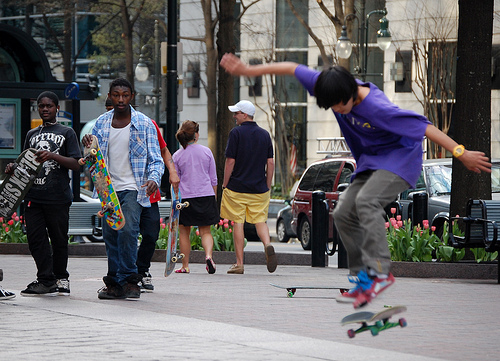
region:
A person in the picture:
[16, 79, 83, 297]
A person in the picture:
[80, 71, 166, 306]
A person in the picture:
[164, 101, 221, 276]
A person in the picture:
[216, 95, 286, 282]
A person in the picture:
[214, 40, 497, 331]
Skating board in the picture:
[337, 303, 421, 346]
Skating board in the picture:
[261, 275, 371, 307]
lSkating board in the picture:
[163, 177, 190, 284]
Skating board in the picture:
[79, 129, 126, 241]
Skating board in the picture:
[0, 127, 49, 237]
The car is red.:
[285, 143, 399, 254]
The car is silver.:
[388, 150, 499, 248]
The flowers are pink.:
[378, 199, 448, 256]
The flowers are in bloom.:
[378, 200, 488, 264]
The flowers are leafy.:
[380, 202, 497, 260]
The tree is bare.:
[403, 1, 458, 161]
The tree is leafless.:
[392, 0, 461, 159]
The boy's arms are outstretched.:
[217, 49, 497, 191]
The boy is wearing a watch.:
[222, 46, 494, 182]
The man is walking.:
[214, 95, 285, 280]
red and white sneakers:
[341, 271, 400, 306]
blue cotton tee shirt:
[292, 67, 434, 185]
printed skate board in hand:
[84, 133, 129, 231]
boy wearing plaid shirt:
[86, 81, 165, 296]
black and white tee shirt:
[22, 125, 80, 198]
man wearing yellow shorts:
[226, 98, 283, 272]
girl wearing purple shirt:
[171, 126, 219, 277]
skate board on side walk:
[276, 278, 348, 296]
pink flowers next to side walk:
[386, 209, 499, 266]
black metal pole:
[311, 188, 326, 268]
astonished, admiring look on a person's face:
[105, 81, 135, 116]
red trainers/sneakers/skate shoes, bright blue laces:
[335, 261, 403, 310]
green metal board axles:
[348, 312, 405, 338]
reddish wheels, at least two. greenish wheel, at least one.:
[342, 313, 413, 346]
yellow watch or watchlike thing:
[450, 141, 467, 159]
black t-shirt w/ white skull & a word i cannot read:
[24, 129, 69, 189]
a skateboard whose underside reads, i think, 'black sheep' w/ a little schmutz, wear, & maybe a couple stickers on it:
[0, 144, 50, 232]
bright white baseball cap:
[224, 94, 263, 118]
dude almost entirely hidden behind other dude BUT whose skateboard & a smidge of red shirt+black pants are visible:
[85, 80, 193, 305]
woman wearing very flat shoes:
[173, 257, 224, 278]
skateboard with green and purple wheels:
[326, 297, 425, 349]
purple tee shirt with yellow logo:
[285, 52, 441, 206]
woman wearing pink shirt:
[156, 103, 231, 285]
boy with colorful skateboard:
[73, 61, 178, 312]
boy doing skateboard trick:
[187, 37, 497, 342]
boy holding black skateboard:
[0, 75, 82, 324]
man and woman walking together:
[166, 86, 298, 286]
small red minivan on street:
[281, 130, 388, 269]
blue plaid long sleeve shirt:
[78, 101, 177, 213]